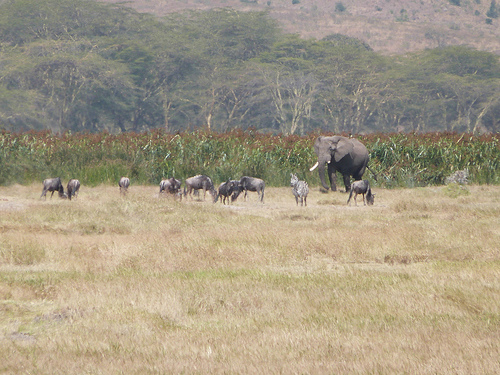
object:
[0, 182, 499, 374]
plains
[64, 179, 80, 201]
water buck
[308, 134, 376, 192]
elephant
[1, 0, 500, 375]
savanna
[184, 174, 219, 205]
water buck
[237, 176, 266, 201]
water buck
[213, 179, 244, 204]
water buck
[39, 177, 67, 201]
water buck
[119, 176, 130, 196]
water buck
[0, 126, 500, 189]
corn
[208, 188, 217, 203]
head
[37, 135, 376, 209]
animals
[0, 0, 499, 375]
field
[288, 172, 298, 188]
head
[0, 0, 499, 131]
trees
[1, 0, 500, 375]
grass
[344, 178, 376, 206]
buck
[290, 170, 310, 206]
pipes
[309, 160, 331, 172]
tusk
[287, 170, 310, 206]
zebra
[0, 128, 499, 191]
plants